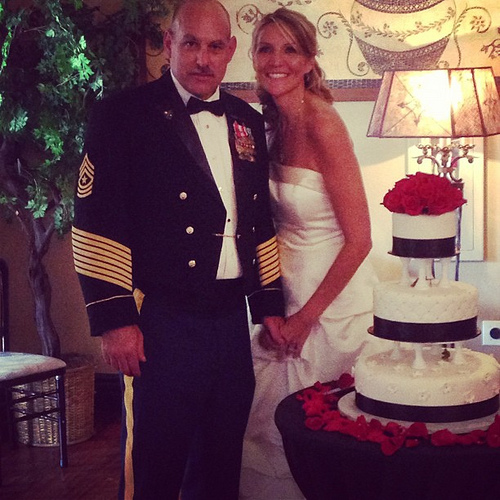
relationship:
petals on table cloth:
[302, 382, 356, 435] [277, 388, 498, 498]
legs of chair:
[0, 369, 66, 476] [1, 256, 75, 467]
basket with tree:
[13, 360, 101, 449] [3, 1, 108, 354]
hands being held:
[256, 309, 313, 362] [278, 321, 283, 326]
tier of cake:
[345, 351, 500, 415] [339, 213, 497, 432]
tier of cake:
[367, 280, 478, 338] [339, 213, 497, 432]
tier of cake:
[392, 211, 467, 254] [339, 213, 497, 432]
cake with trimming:
[339, 213, 497, 432] [354, 394, 499, 425]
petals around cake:
[302, 382, 356, 435] [339, 213, 497, 432]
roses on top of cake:
[369, 172, 474, 216] [339, 213, 497, 432]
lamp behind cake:
[366, 64, 499, 175] [339, 213, 497, 432]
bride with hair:
[243, 7, 391, 489] [276, 10, 336, 95]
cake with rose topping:
[339, 213, 497, 432] [369, 172, 474, 216]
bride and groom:
[243, 7, 391, 489] [72, 5, 284, 493]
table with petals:
[274, 378, 500, 498] [302, 382, 356, 435]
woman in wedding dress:
[243, 7, 391, 489] [248, 155, 386, 499]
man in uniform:
[72, 5, 284, 493] [64, 74, 294, 499]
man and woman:
[72, 5, 284, 493] [243, 7, 391, 489]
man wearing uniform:
[72, 5, 284, 493] [64, 74, 294, 499]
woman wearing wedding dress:
[243, 7, 391, 489] [248, 155, 386, 499]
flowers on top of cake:
[369, 172, 474, 216] [339, 213, 497, 432]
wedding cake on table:
[339, 213, 497, 432] [274, 378, 500, 498]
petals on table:
[302, 382, 356, 435] [274, 378, 500, 498]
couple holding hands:
[74, 4, 387, 499] [256, 309, 313, 362]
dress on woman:
[248, 155, 386, 499] [243, 7, 391, 489]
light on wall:
[421, 86, 462, 115] [146, 5, 499, 421]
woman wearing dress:
[243, 7, 391, 489] [248, 155, 386, 499]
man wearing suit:
[72, 5, 284, 493] [64, 74, 294, 499]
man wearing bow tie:
[72, 5, 284, 493] [186, 95, 230, 122]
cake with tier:
[339, 213, 497, 432] [345, 351, 500, 415]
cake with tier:
[339, 213, 497, 432] [367, 280, 478, 338]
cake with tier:
[339, 213, 497, 432] [392, 211, 467, 254]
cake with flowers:
[339, 213, 497, 432] [369, 172, 474, 216]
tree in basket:
[3, 1, 108, 354] [13, 360, 101, 449]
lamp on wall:
[366, 64, 499, 175] [146, 5, 499, 421]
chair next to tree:
[1, 256, 75, 467] [3, 1, 108, 354]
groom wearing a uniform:
[72, 5, 284, 493] [73, 144, 261, 500]